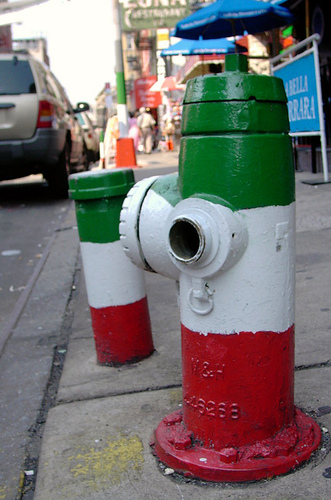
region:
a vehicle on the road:
[1, 48, 80, 188]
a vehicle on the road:
[74, 98, 105, 158]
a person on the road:
[134, 104, 159, 153]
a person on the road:
[124, 106, 143, 156]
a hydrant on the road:
[111, 58, 309, 479]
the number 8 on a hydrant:
[228, 402, 237, 420]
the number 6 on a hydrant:
[216, 400, 225, 424]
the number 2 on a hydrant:
[205, 399, 215, 419]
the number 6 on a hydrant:
[195, 398, 205, 415]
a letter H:
[213, 360, 229, 381]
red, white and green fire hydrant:
[114, 53, 326, 481]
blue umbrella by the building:
[153, 1, 313, 43]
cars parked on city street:
[1, 42, 97, 211]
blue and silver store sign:
[259, 25, 330, 189]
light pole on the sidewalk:
[104, 3, 138, 137]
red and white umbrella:
[147, 71, 191, 98]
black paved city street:
[1, 185, 42, 277]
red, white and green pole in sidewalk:
[60, 159, 164, 370]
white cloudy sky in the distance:
[51, 5, 110, 88]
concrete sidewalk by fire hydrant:
[71, 370, 148, 498]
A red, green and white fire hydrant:
[101, 50, 323, 471]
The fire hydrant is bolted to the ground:
[133, 363, 320, 479]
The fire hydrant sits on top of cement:
[121, 304, 321, 493]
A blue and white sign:
[258, 34, 326, 183]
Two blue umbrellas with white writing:
[138, 2, 304, 73]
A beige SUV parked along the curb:
[5, 48, 92, 186]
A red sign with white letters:
[126, 63, 188, 104]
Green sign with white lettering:
[117, 1, 226, 38]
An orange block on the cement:
[106, 122, 193, 173]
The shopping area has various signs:
[102, 3, 293, 171]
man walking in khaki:
[135, 106, 157, 154]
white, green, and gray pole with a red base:
[112, 1, 136, 166]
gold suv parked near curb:
[1, 49, 87, 192]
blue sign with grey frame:
[268, 36, 329, 168]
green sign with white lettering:
[118, 1, 207, 31]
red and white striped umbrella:
[148, 74, 182, 93]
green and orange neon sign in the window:
[280, 25, 293, 46]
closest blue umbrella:
[169, 1, 292, 40]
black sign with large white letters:
[156, 48, 166, 81]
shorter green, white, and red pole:
[67, 166, 154, 366]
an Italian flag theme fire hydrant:
[165, 61, 306, 479]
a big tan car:
[0, 40, 74, 196]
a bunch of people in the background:
[91, 101, 177, 153]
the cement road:
[0, 179, 46, 405]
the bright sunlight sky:
[52, 0, 113, 85]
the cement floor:
[39, 380, 149, 494]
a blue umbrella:
[170, 2, 297, 41]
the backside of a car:
[0, 75, 64, 136]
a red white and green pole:
[63, 159, 154, 355]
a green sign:
[112, 0, 194, 31]